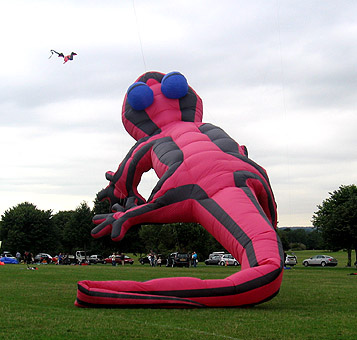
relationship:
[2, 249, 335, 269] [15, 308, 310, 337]
cars parked on grass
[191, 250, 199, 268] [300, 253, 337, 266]
people near car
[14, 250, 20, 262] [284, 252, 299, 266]
person near car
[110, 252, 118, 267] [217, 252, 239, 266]
people near car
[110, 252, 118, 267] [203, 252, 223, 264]
people near vehicle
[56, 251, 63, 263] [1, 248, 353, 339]
people on grass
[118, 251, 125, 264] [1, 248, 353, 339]
people on grass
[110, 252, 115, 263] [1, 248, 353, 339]
people on grass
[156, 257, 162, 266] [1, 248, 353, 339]
people on grass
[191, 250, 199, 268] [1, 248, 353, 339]
people on grass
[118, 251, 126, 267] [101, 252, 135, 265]
people near car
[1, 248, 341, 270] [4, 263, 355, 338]
cars on grass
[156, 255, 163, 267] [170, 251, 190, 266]
people standing beside vehicle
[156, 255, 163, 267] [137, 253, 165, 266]
people standing beside vehicle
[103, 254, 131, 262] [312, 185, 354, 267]
car parked beside tree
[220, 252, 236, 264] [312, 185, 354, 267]
car parked beside tree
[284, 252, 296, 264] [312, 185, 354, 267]
car parked beside tree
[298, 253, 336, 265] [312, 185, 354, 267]
car parked beside tree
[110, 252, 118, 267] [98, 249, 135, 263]
people standing beside car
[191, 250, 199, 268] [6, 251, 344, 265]
people standing by road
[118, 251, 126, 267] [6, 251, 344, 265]
people standing by road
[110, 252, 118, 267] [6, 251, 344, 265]
people standing by road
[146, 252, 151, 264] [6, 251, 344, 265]
person standing by road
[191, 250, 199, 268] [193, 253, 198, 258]
people wearing shirt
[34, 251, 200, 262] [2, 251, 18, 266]
people standing around object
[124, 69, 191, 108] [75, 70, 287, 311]
blue eyes on lizard balloon